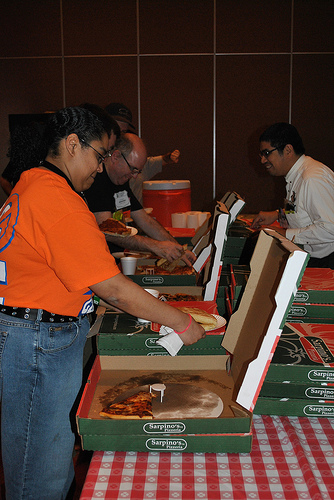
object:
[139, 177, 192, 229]
cooler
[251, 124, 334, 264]
man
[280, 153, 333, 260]
shirt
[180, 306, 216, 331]
pizza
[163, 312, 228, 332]
plate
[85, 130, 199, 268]
man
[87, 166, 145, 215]
tshirt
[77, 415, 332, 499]
tablecloth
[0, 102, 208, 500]
woman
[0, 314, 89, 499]
jeans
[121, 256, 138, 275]
cup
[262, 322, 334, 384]
pizza box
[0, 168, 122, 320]
tshirt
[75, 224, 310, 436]
box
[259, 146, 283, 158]
glasses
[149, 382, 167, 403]
pizza divider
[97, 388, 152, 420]
pizza slice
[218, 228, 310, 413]
cover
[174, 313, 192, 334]
bracelet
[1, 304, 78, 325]
belt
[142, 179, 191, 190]
lid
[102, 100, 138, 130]
hat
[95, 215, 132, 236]
pizza slice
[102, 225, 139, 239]
plate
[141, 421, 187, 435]
logo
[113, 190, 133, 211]
name tag